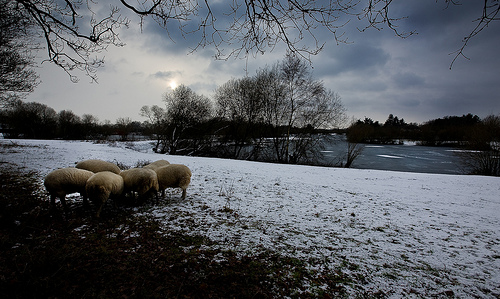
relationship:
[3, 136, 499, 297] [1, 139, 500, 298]
snow covers ground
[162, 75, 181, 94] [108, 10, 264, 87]
sun behind clouds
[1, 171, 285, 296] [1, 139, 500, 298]
leaves on ground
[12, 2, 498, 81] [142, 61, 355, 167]
branches of trees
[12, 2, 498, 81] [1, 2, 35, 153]
branches of tree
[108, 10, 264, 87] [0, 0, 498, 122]
clouds in sky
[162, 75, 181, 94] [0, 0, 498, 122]
sun in sky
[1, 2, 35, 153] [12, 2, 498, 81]
tree has branches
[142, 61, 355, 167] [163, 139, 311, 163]
trees have trunks